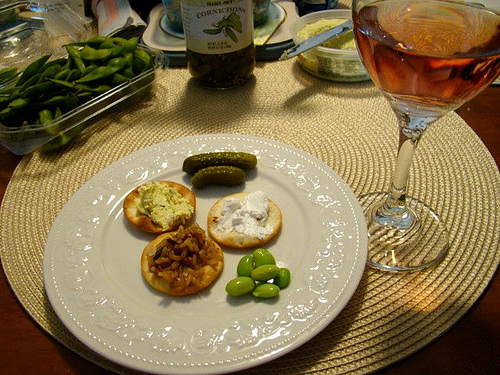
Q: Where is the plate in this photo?
A: On mat.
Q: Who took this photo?
A: Photographer.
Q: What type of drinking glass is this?
A: Wine glass.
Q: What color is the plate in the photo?
A: White.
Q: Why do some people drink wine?
A: To relax.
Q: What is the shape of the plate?
A: Round.